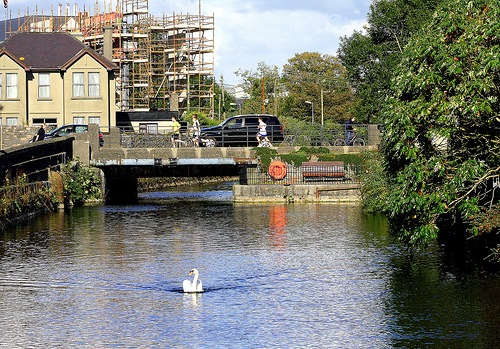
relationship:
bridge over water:
[72, 120, 380, 202] [0, 180, 499, 347]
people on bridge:
[144, 73, 308, 139] [48, 115, 389, 182]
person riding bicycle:
[340, 110, 368, 143] [178, 133, 220, 147]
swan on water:
[172, 257, 215, 302] [255, 262, 381, 333]